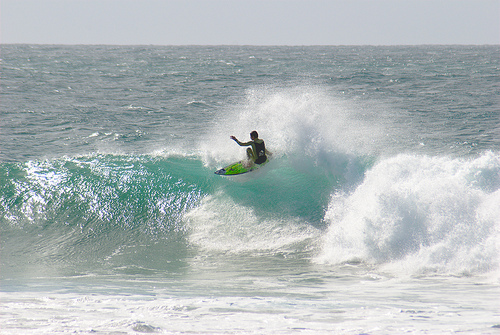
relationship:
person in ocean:
[227, 128, 278, 173] [1, 40, 499, 334]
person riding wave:
[227, 128, 278, 173] [1, 145, 498, 254]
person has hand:
[227, 128, 278, 173] [229, 132, 237, 143]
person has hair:
[227, 128, 278, 173] [250, 129, 258, 140]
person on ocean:
[227, 128, 278, 173] [1, 40, 499, 334]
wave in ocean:
[1, 145, 498, 254] [1, 40, 499, 334]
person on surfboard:
[227, 128, 278, 173] [213, 153, 275, 177]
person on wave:
[227, 128, 278, 173] [1, 145, 498, 254]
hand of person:
[229, 132, 237, 143] [227, 128, 278, 173]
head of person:
[246, 127, 260, 141] [227, 128, 278, 173]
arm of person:
[228, 135, 255, 147] [227, 128, 278, 173]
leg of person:
[243, 146, 256, 165] [227, 128, 278, 173]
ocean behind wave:
[1, 40, 499, 334] [1, 145, 498, 254]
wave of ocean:
[1, 145, 498, 254] [1, 40, 499, 334]